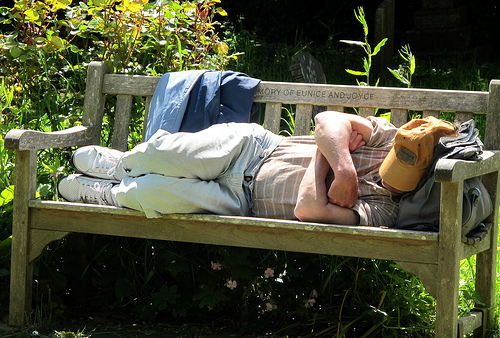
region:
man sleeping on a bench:
[5, 103, 490, 265]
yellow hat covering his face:
[363, 106, 455, 203]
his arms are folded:
[292, 99, 389, 229]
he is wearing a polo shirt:
[256, 109, 409, 237]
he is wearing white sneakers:
[42, 117, 142, 212]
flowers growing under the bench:
[174, 251, 341, 331]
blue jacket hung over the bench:
[145, 59, 265, 141]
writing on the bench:
[224, 71, 401, 112]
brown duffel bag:
[396, 146, 491, 252]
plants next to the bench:
[0, 2, 221, 187]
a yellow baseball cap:
[378, 115, 450, 191]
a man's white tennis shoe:
[72, 139, 128, 180]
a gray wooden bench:
[3, 55, 498, 337]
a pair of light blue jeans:
[145, 67, 208, 140]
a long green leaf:
[340, 10, 392, 90]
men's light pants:
[112, 119, 276, 214]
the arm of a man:
[308, 101, 395, 183]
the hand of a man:
[327, 167, 362, 208]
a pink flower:
[257, 265, 274, 280]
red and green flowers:
[187, 5, 215, 44]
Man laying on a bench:
[59, 107, 439, 222]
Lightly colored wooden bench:
[14, 48, 499, 313]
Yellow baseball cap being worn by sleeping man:
[370, 110, 446, 197]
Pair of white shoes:
[72, 133, 129, 202]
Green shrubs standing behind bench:
[25, 11, 243, 98]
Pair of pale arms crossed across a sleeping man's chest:
[306, 103, 372, 230]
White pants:
[114, 120, 261, 222]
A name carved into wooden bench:
[250, 80, 390, 101]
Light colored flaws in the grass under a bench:
[189, 218, 298, 335]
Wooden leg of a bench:
[432, 153, 467, 330]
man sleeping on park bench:
[17, 42, 489, 335]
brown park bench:
[0, 77, 498, 326]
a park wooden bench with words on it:
[6, 75, 478, 322]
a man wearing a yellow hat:
[375, 111, 453, 193]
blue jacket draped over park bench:
[141, 67, 271, 126]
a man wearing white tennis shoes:
[59, 139, 134, 201]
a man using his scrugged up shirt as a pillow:
[441, 120, 483, 162]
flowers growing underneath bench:
[0, 234, 476, 336]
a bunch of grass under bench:
[41, 240, 497, 336]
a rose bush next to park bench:
[2, 0, 223, 167]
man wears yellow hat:
[381, 114, 453, 202]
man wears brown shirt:
[228, 120, 406, 243]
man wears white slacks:
[143, 98, 284, 241]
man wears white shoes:
[69, 138, 128, 216]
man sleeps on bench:
[26, 59, 498, 318]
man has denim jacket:
[119, 66, 266, 132]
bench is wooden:
[23, 55, 495, 322]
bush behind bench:
[2, 4, 239, 221]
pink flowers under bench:
[195, 254, 276, 303]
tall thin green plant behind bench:
[334, 3, 436, 116]